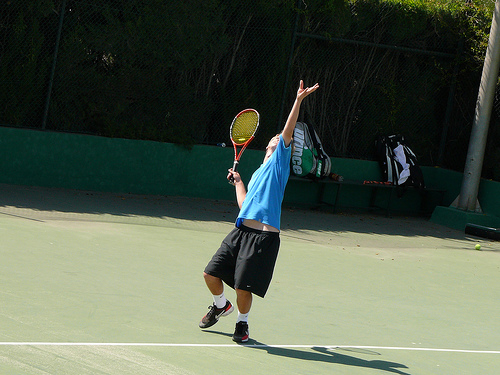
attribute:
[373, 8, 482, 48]
leaves — green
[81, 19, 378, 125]
fence — metal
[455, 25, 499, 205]
pole — gey, large, metal, silver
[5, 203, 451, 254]
ground — grey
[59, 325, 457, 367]
lines — white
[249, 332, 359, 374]
shadow — ground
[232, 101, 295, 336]
man — playing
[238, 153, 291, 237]
shirt — blue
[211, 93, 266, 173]
racket — red, black, tennis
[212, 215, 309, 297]
shorts — black, athletic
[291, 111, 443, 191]
bags — larger, green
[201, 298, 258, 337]
tennis shoes — black, white, red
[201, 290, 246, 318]
socks — long, white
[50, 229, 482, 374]
court — tennis, green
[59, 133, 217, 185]
wall — green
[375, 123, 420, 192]
bag — black, white